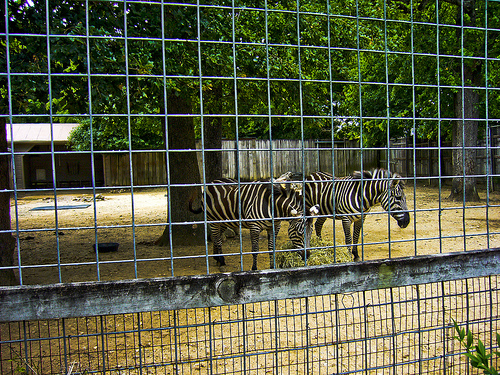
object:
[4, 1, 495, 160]
fence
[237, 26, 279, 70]
leaves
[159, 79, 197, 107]
branch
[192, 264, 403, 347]
ground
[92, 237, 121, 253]
container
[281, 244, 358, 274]
grass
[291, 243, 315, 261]
feeding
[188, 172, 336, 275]
zebra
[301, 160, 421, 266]
zebra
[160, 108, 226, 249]
trunk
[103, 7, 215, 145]
tree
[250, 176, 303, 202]
short hair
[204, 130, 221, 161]
woods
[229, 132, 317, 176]
board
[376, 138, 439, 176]
gate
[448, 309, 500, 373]
plant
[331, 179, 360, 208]
black stripes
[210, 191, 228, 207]
white stripes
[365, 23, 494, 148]
trees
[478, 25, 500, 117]
corner